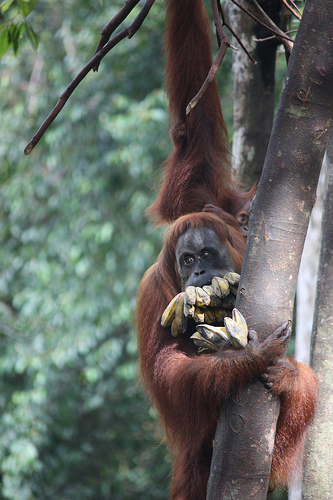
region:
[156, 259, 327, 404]
the bananas are visible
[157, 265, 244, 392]
the bananas are visible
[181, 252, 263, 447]
the bananas are visible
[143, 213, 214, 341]
the bananas are visible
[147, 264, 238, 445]
an orangutan is visible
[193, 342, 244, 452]
an orangutan is visible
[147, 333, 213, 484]
an orangutan is visible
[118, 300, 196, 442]
an orangutan is visible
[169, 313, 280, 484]
an orangutan is visible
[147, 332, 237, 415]
an orangutan is visible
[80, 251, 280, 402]
an orangutan is visible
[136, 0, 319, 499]
An orangutan hanging from a tree.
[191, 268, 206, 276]
Large nostrils on an animal.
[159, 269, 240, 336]
Many bananas sticking out of an animals mouth.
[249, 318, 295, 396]
Hands of an animal.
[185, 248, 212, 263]
Eyes of an orangutan.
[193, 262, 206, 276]
Nose of an orangutan.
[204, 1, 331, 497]
A tall thin tree an orangutan is hanging from.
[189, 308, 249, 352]
Bananas an orangutan is holding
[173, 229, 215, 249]
Forehead of an orangutan.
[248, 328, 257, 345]
Thumb on an orangutans right hand.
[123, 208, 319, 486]
Ape holding on to a tree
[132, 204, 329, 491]
Orangutan in a tree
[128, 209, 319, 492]
Orangutan with bananas in its mouth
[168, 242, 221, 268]
Eyes of an ape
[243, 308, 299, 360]
Hand of an ape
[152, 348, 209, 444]
Fur of an ape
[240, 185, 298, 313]
Trunk of a tree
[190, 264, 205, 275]
Nose of an ape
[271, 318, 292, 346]
Two fingers of an ape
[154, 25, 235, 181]
Arm of an ape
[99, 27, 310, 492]
furry red monkey in tree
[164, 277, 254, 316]
bunch of bananas in monkey mouth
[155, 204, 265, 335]
red monkey with black face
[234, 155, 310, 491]
smooth brown tree trunk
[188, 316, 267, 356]
bunch of bananas in monkey hand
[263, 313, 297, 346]
two black monkey fingers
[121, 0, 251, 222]
long furry red monkey arm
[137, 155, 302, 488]
monkey with bananas climbing tree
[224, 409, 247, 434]
circular indention on tree trunk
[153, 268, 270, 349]
two bunches of yellow bananas